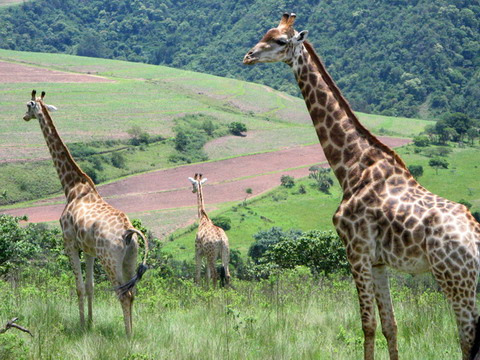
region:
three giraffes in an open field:
[2, 3, 475, 358]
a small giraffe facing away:
[184, 175, 230, 292]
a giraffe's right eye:
[271, 37, 290, 46]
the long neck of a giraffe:
[294, 60, 383, 181]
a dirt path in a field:
[3, 133, 414, 229]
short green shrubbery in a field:
[0, 209, 351, 287]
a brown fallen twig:
[0, 313, 34, 342]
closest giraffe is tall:
[241, 10, 473, 355]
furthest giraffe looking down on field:
[179, 164, 235, 290]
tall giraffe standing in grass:
[16, 80, 149, 335]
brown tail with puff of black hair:
[120, 219, 152, 285]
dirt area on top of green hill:
[0, 50, 120, 89]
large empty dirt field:
[2, 127, 399, 223]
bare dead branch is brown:
[0, 302, 39, 354]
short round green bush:
[274, 168, 292, 189]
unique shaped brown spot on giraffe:
[375, 192, 396, 222]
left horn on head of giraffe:
[182, 170, 197, 184]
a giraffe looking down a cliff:
[180, 163, 241, 290]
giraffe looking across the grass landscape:
[21, 86, 155, 343]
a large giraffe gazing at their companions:
[232, 7, 478, 359]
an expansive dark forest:
[21, 2, 479, 143]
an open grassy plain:
[4, 45, 429, 215]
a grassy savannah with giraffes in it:
[7, 270, 466, 355]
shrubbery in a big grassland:
[243, 219, 336, 291]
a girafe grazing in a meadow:
[178, 166, 238, 292]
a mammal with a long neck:
[17, 82, 171, 330]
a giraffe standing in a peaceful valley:
[232, 9, 478, 358]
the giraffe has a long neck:
[295, 43, 382, 180]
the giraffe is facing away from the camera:
[187, 169, 237, 292]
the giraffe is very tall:
[237, 9, 477, 354]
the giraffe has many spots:
[315, 128, 401, 224]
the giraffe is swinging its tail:
[112, 223, 152, 302]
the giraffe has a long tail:
[212, 233, 228, 286]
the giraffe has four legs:
[61, 245, 149, 345]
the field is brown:
[0, 57, 91, 82]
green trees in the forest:
[81, 8, 229, 57]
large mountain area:
[46, 14, 239, 53]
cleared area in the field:
[9, 56, 120, 88]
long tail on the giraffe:
[126, 261, 156, 288]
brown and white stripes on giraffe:
[380, 214, 444, 245]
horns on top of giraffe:
[275, 2, 319, 33]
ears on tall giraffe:
[293, 19, 316, 43]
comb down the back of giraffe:
[345, 99, 412, 171]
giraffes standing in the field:
[26, 15, 440, 268]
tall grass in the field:
[164, 318, 236, 346]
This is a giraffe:
[182, 157, 246, 303]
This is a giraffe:
[13, 76, 168, 355]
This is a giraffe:
[243, 8, 474, 348]